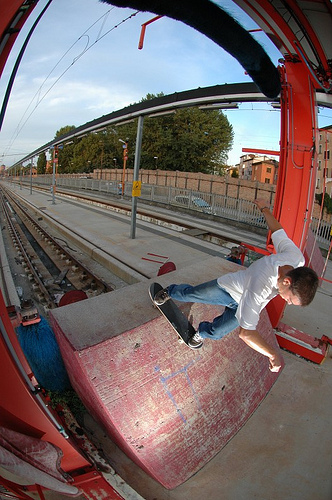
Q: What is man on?
A: Skateboard.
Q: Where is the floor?
A: Below ramp.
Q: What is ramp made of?
A: Concrete.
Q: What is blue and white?
A: Sky.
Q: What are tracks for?
A: Train.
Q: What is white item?
A: T-shirt.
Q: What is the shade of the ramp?
A: Red.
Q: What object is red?
A: Ramp.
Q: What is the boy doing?
A: Skateboarding.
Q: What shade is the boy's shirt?
A: White.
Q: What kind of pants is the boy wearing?
A: Jean.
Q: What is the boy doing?
A: Skateboard tricks.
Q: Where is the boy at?
A: Train track.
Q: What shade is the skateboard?
A: Black.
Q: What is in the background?
A: Gate.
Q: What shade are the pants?
A: Blue.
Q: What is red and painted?
A: The ramp.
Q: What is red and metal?
A: The support post.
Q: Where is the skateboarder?
A: Going down the ramp.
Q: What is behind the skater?
A: Train tracks.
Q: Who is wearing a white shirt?
A: The man.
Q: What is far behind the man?
A: Trees.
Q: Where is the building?
A: On the side of the road.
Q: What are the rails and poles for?
A: The trains.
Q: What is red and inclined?
A: The ramp.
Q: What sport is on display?
A: Skateboarding.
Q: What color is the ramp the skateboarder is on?
A: Red.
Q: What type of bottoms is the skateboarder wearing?
A: Jeans.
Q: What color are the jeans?
A: Blue.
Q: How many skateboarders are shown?
A: One.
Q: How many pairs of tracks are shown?
A: One.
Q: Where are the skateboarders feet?
A: On skateboard.